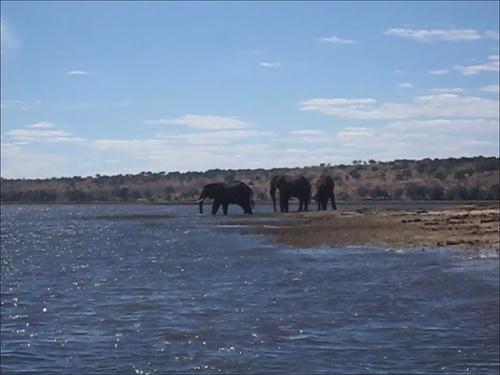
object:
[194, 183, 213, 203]
head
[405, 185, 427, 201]
tree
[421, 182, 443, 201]
tree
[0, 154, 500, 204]
field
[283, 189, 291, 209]
grey leg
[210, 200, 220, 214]
legs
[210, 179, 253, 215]
body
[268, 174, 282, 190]
head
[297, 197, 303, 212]
legs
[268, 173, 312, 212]
elephant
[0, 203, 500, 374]
water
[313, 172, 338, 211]
elephant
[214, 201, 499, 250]
shore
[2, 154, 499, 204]
hill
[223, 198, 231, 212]
leg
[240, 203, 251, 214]
leg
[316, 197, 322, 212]
leg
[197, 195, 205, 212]
trunk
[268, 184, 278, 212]
trunk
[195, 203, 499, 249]
sand bar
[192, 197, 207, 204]
tusk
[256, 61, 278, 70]
clouds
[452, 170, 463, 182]
tree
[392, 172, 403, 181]
tree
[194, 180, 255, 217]
elephant